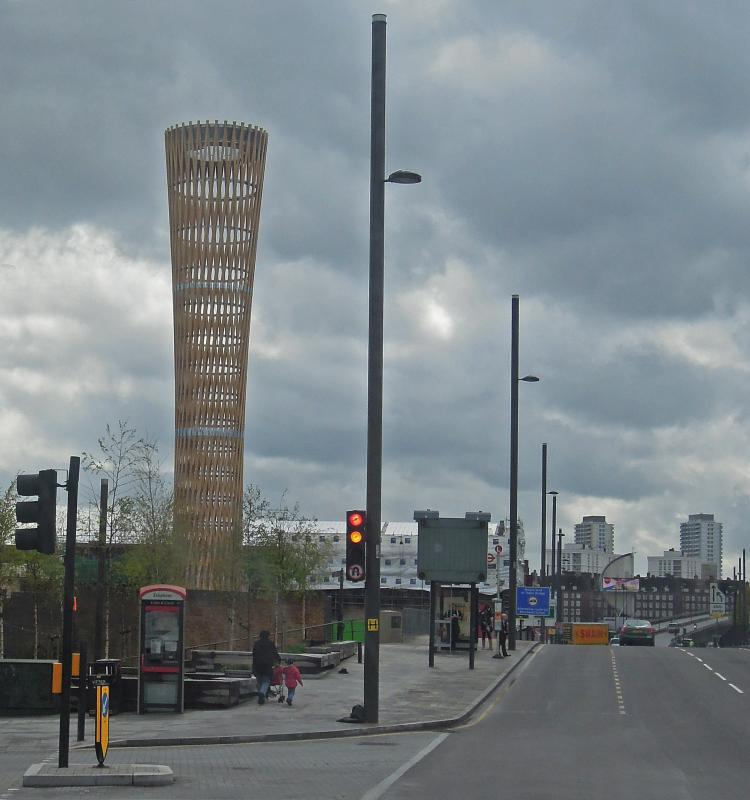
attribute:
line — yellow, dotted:
[607, 642, 632, 719]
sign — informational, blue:
[514, 583, 560, 622]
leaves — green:
[267, 531, 316, 585]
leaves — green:
[121, 553, 153, 581]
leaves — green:
[117, 496, 156, 550]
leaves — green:
[269, 531, 316, 563]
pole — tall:
[124, 233, 503, 569]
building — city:
[123, 98, 353, 636]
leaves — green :
[52, 560, 155, 662]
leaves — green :
[217, 505, 300, 605]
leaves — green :
[229, 516, 339, 691]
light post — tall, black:
[506, 293, 520, 648]